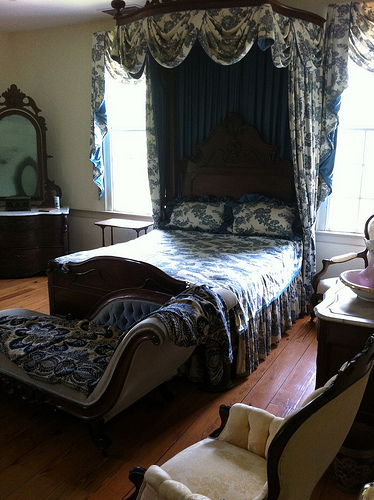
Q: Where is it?
A: This is at the bedroom.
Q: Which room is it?
A: It is a bedroom.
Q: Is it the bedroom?
A: Yes, it is the bedroom.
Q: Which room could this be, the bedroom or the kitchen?
A: It is the bedroom.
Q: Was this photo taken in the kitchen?
A: No, the picture was taken in the bedroom.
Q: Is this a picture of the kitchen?
A: No, the picture is showing the bedroom.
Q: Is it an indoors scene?
A: Yes, it is indoors.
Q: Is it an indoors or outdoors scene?
A: It is indoors.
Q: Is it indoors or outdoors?
A: It is indoors.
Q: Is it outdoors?
A: No, it is indoors.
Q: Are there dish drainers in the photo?
A: No, there are no dish drainers.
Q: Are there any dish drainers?
A: No, there are no dish drainers.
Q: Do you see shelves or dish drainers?
A: No, there are no dish drainers or shelves.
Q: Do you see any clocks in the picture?
A: No, there are no clocks.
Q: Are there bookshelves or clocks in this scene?
A: No, there are no clocks or bookshelves.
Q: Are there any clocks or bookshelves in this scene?
A: No, there are no clocks or bookshelves.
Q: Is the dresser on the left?
A: Yes, the dresser is on the left of the image.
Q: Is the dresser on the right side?
A: No, the dresser is on the left of the image.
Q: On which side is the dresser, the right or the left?
A: The dresser is on the left of the image.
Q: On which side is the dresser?
A: The dresser is on the left of the image.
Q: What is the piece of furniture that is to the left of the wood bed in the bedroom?
A: The piece of furniture is a dresser.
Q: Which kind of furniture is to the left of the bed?
A: The piece of furniture is a dresser.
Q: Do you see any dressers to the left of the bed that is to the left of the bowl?
A: Yes, there is a dresser to the left of the bed.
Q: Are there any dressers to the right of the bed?
A: No, the dresser is to the left of the bed.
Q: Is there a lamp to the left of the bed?
A: No, there is a dresser to the left of the bed.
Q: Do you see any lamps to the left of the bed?
A: No, there is a dresser to the left of the bed.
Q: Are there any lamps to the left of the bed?
A: No, there is a dresser to the left of the bed.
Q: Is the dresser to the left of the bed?
A: Yes, the dresser is to the left of the bed.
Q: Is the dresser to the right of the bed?
A: No, the dresser is to the left of the bed.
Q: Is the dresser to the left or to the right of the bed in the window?
A: The dresser is to the left of the bed.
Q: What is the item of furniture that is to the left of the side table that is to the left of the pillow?
A: The piece of furniture is a dresser.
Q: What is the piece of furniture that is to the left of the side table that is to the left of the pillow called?
A: The piece of furniture is a dresser.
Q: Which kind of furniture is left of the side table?
A: The piece of furniture is a dresser.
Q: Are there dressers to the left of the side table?
A: Yes, there is a dresser to the left of the side table.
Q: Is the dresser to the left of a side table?
A: Yes, the dresser is to the left of a side table.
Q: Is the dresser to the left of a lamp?
A: No, the dresser is to the left of a side table.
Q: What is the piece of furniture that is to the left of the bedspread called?
A: The piece of furniture is a dresser.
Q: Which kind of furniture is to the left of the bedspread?
A: The piece of furniture is a dresser.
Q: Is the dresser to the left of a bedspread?
A: Yes, the dresser is to the left of a bedspread.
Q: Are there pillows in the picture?
A: Yes, there is a pillow.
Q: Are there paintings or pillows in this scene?
A: Yes, there is a pillow.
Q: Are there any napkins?
A: No, there are no napkins.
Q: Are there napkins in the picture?
A: No, there are no napkins.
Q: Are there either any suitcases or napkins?
A: No, there are no napkins or suitcases.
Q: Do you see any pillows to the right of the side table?
A: Yes, there is a pillow to the right of the side table.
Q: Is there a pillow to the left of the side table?
A: No, the pillow is to the right of the side table.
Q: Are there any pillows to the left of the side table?
A: No, the pillow is to the right of the side table.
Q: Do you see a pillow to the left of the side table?
A: No, the pillow is to the right of the side table.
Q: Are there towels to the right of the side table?
A: No, there is a pillow to the right of the side table.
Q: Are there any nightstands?
A: No, there are no nightstands.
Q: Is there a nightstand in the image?
A: No, there are no nightstands.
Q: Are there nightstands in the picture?
A: No, there are no nightstands.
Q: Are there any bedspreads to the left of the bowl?
A: Yes, there is a bedspread to the left of the bowl.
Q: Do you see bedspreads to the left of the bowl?
A: Yes, there is a bedspread to the left of the bowl.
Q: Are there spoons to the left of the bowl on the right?
A: No, there is a bedspread to the left of the bowl.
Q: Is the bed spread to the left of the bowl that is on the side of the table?
A: Yes, the bed spread is to the left of the bowl.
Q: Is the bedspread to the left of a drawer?
A: No, the bedspread is to the left of the bowl.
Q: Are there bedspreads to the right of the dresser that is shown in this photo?
A: Yes, there is a bedspread to the right of the dresser.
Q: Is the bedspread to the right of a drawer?
A: No, the bedspread is to the right of a dresser.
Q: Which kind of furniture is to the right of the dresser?
A: The piece of furniture is a side table.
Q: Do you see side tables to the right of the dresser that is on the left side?
A: Yes, there is a side table to the right of the dresser.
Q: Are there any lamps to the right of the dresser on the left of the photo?
A: No, there is a side table to the right of the dresser.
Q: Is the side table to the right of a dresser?
A: Yes, the side table is to the right of a dresser.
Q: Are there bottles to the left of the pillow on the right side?
A: No, there is a side table to the left of the pillow.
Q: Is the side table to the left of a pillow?
A: Yes, the side table is to the left of a pillow.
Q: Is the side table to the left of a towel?
A: No, the side table is to the left of a pillow.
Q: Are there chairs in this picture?
A: Yes, there is a chair.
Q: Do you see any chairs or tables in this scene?
A: Yes, there is a chair.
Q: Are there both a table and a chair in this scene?
A: Yes, there are both a chair and a table.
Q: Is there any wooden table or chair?
A: Yes, there is a wood chair.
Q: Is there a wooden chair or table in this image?
A: Yes, there is a wood chair.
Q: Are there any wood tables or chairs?
A: Yes, there is a wood chair.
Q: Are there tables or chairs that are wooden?
A: Yes, the chair is wooden.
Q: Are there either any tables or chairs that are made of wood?
A: Yes, the chair is made of wood.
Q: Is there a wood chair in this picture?
A: Yes, there is a wood chair.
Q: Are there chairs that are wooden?
A: Yes, there is a chair that is wooden.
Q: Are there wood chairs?
A: Yes, there is a chair that is made of wood.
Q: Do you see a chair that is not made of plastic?
A: Yes, there is a chair that is made of wood.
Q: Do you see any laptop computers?
A: No, there are no laptop computers.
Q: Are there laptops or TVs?
A: No, there are no laptops or tvs.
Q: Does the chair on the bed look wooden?
A: Yes, the chair is wooden.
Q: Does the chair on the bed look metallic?
A: No, the chair is wooden.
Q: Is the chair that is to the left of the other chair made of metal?
A: No, the chair is made of wood.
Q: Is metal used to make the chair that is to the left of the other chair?
A: No, the chair is made of wood.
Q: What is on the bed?
A: The chair is on the bed.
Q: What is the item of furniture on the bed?
A: The piece of furniture is a chair.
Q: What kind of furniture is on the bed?
A: The piece of furniture is a chair.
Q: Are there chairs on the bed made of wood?
A: Yes, there is a chair on the bed.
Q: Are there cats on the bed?
A: No, there is a chair on the bed.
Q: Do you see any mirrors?
A: Yes, there is a mirror.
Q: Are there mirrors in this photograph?
A: Yes, there is a mirror.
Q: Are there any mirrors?
A: Yes, there is a mirror.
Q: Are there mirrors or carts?
A: Yes, there is a mirror.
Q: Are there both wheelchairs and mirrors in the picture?
A: No, there is a mirror but no wheelchairs.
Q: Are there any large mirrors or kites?
A: Yes, there is a large mirror.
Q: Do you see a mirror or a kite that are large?
A: Yes, the mirror is large.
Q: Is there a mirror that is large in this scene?
A: Yes, there is a large mirror.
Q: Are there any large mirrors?
A: Yes, there is a large mirror.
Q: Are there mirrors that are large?
A: Yes, there is a mirror that is large.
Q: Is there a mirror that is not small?
A: Yes, there is a large mirror.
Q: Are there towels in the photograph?
A: No, there are no towels.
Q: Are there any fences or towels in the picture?
A: No, there are no towels or fences.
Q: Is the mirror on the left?
A: Yes, the mirror is on the left of the image.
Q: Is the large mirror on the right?
A: No, the mirror is on the left of the image.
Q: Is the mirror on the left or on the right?
A: The mirror is on the left of the image.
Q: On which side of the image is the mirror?
A: The mirror is on the left of the image.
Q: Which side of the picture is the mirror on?
A: The mirror is on the left of the image.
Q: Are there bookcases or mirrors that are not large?
A: No, there is a mirror but it is large.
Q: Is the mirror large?
A: Yes, the mirror is large.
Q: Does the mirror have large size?
A: Yes, the mirror is large.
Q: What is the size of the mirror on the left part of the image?
A: The mirror is large.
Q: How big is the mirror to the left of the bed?
A: The mirror is large.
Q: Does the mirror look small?
A: No, the mirror is large.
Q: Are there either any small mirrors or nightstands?
A: No, there is a mirror but it is large.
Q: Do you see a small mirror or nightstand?
A: No, there is a mirror but it is large.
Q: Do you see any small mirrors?
A: No, there is a mirror but it is large.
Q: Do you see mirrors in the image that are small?
A: No, there is a mirror but it is large.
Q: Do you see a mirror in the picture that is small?
A: No, there is a mirror but it is large.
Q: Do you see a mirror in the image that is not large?
A: No, there is a mirror but it is large.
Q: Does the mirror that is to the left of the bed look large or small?
A: The mirror is large.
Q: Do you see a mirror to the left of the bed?
A: Yes, there is a mirror to the left of the bed.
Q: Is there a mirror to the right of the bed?
A: No, the mirror is to the left of the bed.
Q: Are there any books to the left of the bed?
A: No, there is a mirror to the left of the bed.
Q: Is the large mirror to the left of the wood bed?
A: Yes, the mirror is to the left of the bed.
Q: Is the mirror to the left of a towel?
A: No, the mirror is to the left of the bed.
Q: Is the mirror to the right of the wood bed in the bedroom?
A: No, the mirror is to the left of the bed.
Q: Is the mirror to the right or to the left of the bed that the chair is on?
A: The mirror is to the left of the bed.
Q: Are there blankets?
A: Yes, there is a blanket.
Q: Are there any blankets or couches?
A: Yes, there is a blanket.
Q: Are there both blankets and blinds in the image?
A: No, there is a blanket but no blinds.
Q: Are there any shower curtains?
A: No, there are no shower curtains.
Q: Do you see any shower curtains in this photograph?
A: No, there are no shower curtains.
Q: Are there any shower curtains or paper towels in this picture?
A: No, there are no shower curtains or paper towels.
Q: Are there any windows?
A: Yes, there is a window.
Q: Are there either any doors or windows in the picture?
A: Yes, there is a window.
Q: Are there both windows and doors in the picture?
A: No, there is a window but no doors.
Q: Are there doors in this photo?
A: No, there are no doors.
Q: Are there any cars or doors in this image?
A: No, there are no doors or cars.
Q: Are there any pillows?
A: Yes, there is a pillow.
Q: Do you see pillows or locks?
A: Yes, there is a pillow.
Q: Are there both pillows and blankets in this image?
A: Yes, there are both a pillow and a blanket.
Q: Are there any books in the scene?
A: No, there are no books.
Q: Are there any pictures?
A: No, there are no pictures.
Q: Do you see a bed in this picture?
A: Yes, there is a bed.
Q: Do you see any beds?
A: Yes, there is a bed.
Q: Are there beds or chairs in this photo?
A: Yes, there is a bed.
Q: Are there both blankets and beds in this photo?
A: Yes, there are both a bed and a blanket.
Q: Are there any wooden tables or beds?
A: Yes, there is a wood bed.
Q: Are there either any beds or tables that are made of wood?
A: Yes, the bed is made of wood.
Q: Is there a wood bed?
A: Yes, there is a bed that is made of wood.